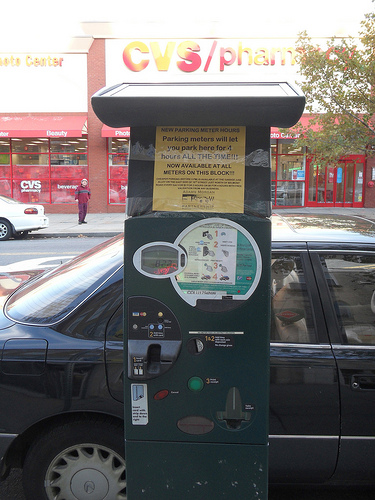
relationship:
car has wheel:
[1, 214, 373, 499] [24, 415, 124, 499]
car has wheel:
[0, 193, 47, 244] [0, 218, 13, 241]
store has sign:
[1, 0, 373, 216] [121, 39, 353, 83]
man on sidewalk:
[74, 179, 93, 224] [29, 205, 374, 237]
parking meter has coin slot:
[92, 79, 308, 499] [183, 336, 207, 355]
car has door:
[1, 214, 373, 499] [305, 241, 373, 494]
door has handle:
[305, 241, 373, 494] [345, 369, 374, 389]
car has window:
[1, 214, 373, 499] [323, 251, 374, 347]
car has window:
[1, 214, 373, 499] [266, 251, 315, 346]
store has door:
[1, 0, 373, 216] [301, 155, 368, 208]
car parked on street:
[0, 193, 47, 244] [0, 236, 116, 275]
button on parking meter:
[188, 378, 204, 394] [92, 79, 308, 499]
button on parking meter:
[153, 389, 171, 403] [92, 79, 308, 499]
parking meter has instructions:
[92, 79, 308, 499] [172, 216, 263, 305]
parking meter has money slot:
[92, 79, 308, 499] [128, 355, 177, 367]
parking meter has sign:
[92, 79, 308, 499] [152, 123, 249, 220]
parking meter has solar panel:
[92, 79, 308, 499] [98, 82, 299, 99]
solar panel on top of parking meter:
[98, 82, 299, 99] [92, 79, 308, 499]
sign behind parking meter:
[121, 39, 353, 83] [92, 79, 308, 499]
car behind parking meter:
[1, 214, 373, 499] [92, 79, 308, 499]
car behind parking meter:
[0, 193, 47, 244] [92, 79, 308, 499]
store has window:
[1, 0, 373, 216] [0, 138, 11, 169]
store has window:
[1, 0, 373, 216] [13, 137, 51, 168]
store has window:
[1, 0, 373, 216] [50, 137, 89, 164]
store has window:
[1, 0, 373, 216] [108, 137, 131, 166]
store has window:
[1, 0, 373, 216] [269, 139, 307, 208]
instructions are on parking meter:
[172, 216, 263, 305] [92, 79, 308, 499]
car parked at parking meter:
[1, 214, 373, 499] [92, 79, 308, 499]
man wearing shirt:
[74, 179, 93, 224] [76, 187, 92, 206]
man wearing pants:
[74, 179, 93, 224] [77, 202, 90, 222]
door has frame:
[301, 155, 368, 208] [305, 151, 365, 164]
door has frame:
[301, 155, 368, 208] [306, 200, 364, 210]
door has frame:
[301, 155, 368, 208] [362, 155, 367, 202]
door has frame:
[301, 155, 368, 208] [305, 154, 313, 205]